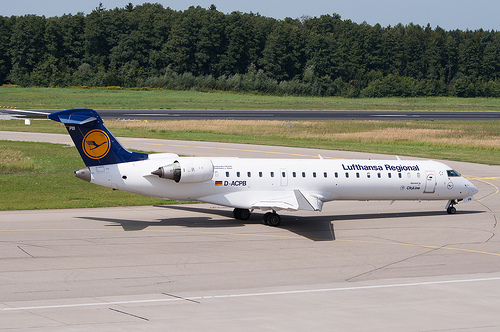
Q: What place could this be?
A: It is a runway.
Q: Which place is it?
A: It is a runway.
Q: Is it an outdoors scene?
A: Yes, it is outdoors.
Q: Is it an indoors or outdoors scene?
A: It is outdoors.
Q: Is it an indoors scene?
A: No, it is outdoors.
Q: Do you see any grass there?
A: Yes, there is grass.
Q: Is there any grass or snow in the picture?
A: Yes, there is grass.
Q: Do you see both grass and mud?
A: No, there is grass but no mud.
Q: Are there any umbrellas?
A: No, there are no umbrellas.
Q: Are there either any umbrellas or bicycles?
A: No, there are no umbrellas or bicycles.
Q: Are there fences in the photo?
A: No, there are no fences.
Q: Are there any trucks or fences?
A: No, there are no fences or trucks.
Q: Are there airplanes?
A: Yes, there is an airplane.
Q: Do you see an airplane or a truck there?
A: Yes, there is an airplane.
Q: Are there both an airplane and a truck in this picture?
A: No, there is an airplane but no trucks.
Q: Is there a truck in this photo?
A: No, there are no trucks.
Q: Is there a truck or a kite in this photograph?
A: No, there are no trucks or kites.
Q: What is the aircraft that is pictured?
A: The aircraft is an airplane.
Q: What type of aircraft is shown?
A: The aircraft is an airplane.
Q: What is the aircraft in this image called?
A: The aircraft is an airplane.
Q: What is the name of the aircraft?
A: The aircraft is an airplane.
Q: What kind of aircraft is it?
A: The aircraft is an airplane.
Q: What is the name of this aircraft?
A: This is an airplane.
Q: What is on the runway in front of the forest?
A: The plane is on the runway.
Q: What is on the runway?
A: The plane is on the runway.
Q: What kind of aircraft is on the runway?
A: The aircraft is an airplane.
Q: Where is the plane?
A: The plane is on the runway.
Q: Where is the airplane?
A: The plane is on the runway.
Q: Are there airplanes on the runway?
A: Yes, there is an airplane on the runway.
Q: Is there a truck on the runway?
A: No, there is an airplane on the runway.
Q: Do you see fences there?
A: No, there are no fences.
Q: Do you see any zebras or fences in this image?
A: No, there are no fences or zebras.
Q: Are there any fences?
A: No, there are no fences.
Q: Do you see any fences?
A: No, there are no fences.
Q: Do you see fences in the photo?
A: No, there are no fences.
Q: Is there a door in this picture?
A: Yes, there is a door.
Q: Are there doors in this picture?
A: Yes, there is a door.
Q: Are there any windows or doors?
A: Yes, there is a door.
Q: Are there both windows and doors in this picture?
A: Yes, there are both a door and a window.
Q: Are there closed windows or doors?
A: Yes, there is a closed door.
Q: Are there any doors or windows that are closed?
A: Yes, the door is closed.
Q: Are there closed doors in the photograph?
A: Yes, there is a closed door.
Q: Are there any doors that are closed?
A: Yes, there is a closed door.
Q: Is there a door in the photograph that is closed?
A: Yes, there is a door that is closed.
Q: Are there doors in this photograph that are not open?
A: Yes, there is an closed door.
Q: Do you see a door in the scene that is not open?
A: Yes, there is an closed door.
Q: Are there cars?
A: No, there are no cars.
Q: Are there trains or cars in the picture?
A: No, there are no cars or trains.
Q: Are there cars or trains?
A: No, there are no cars or trains.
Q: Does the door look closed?
A: Yes, the door is closed.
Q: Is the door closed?
A: Yes, the door is closed.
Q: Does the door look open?
A: No, the door is closed.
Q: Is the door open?
A: No, the door is closed.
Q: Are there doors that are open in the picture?
A: No, there is a door but it is closed.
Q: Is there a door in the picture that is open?
A: No, there is a door but it is closed.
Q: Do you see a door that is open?
A: No, there is a door but it is closed.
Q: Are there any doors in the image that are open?
A: No, there is a door but it is closed.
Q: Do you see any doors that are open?
A: No, there is a door but it is closed.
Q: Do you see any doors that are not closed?
A: No, there is a door but it is closed.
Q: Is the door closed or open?
A: The door is closed.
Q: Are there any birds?
A: No, there are no birds.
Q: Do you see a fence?
A: No, there are no fences.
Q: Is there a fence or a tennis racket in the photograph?
A: No, there are no fences or rackets.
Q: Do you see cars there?
A: No, there are no cars.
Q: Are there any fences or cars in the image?
A: No, there are no cars or fences.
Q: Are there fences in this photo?
A: No, there are no fences.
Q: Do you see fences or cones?
A: No, there are no fences or cones.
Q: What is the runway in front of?
A: The runway is in front of the forest.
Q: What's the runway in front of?
A: The runway is in front of the forest.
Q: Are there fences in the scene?
A: No, there are no fences.